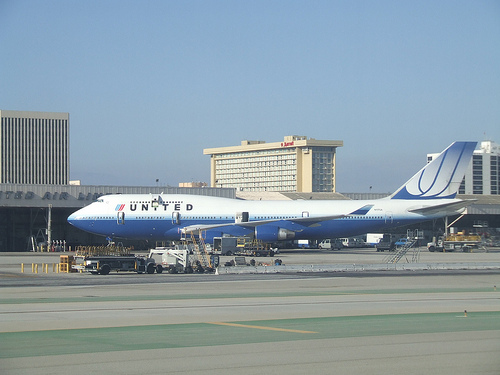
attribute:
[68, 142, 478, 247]
airplane — blue, white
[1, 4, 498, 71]
sky — blue, clear